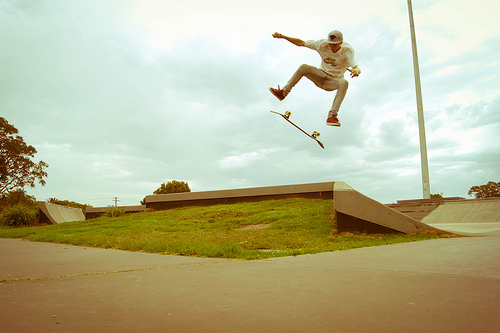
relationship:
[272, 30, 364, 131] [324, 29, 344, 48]
man wearing hat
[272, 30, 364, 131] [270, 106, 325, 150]
man riding skateboard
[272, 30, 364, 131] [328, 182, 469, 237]
man going off ramp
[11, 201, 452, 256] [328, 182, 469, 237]
grass next to ramp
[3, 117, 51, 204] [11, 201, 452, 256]
tree by grass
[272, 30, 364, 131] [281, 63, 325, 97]
man has leg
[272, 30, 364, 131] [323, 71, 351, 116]
man has leg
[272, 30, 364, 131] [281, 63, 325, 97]
man has a leg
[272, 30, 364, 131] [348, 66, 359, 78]
man has hand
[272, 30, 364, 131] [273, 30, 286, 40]
man has hand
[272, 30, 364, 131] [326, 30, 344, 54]
man has head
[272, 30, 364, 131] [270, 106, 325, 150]
man jumping off skateboard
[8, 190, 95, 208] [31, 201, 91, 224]
bush above ramp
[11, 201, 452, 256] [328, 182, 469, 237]
grass in middle of ramp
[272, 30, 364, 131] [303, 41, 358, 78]
man wearing shirt